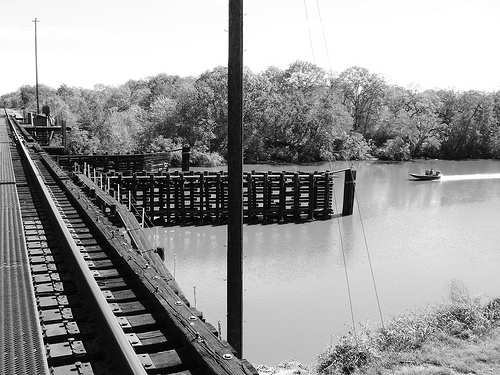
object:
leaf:
[163, 81, 179, 92]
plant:
[150, 73, 217, 142]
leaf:
[208, 70, 218, 82]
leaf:
[133, 91, 152, 104]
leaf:
[267, 90, 286, 104]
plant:
[373, 134, 411, 163]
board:
[150, 347, 190, 371]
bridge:
[0, 106, 256, 374]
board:
[126, 313, 157, 326]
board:
[136, 327, 169, 347]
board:
[29, 255, 46, 263]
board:
[30, 263, 47, 273]